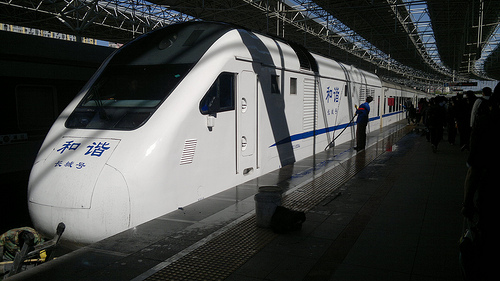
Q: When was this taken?
A: Daytime.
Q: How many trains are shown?
A: 1.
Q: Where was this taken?
A: A train station.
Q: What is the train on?
A: A track.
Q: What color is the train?
A: White.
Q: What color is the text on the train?
A: Blue.